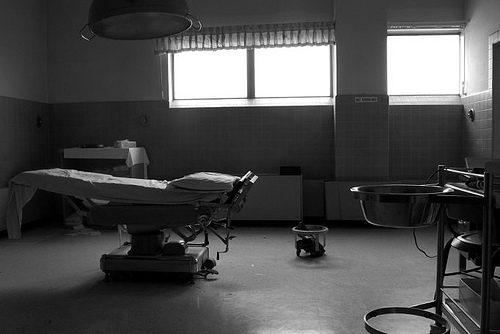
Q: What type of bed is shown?
A: Hospital bed.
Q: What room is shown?
A: Operating room.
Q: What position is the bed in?
A: Foot raised.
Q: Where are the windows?
A: Back wall.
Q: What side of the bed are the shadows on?
A: Left side.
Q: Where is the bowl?
A: Bottom right of the image.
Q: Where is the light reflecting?
A: Floor.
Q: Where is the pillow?
A: Head of the bed.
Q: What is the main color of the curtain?
A: White.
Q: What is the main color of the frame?
A: White.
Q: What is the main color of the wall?
A: White.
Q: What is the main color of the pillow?
A: White.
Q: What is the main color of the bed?
A: White.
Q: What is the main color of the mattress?
A: White.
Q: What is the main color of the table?
A: White.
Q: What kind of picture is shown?
A: Black and white.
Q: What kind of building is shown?
A: Medical facility.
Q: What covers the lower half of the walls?
A: Tiles.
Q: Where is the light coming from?
A: Windows.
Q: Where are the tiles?
A: On the walls.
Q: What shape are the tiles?
A: Square.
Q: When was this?
A: Daytime.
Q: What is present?
A: A bed.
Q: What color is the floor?
A: Grey.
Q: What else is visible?
A: A window.